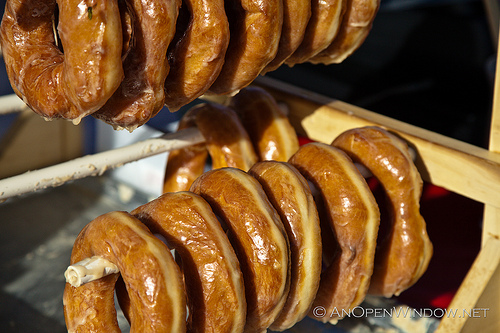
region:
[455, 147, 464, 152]
part of a table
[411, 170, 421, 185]
edge of a table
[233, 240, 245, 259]
part of a cake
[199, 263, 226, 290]
edge of a cake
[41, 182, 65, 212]
part of a rail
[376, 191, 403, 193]
edge of a cake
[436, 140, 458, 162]
edge of a table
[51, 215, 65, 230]
part of a table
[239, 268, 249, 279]
edge of a cake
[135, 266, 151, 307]
part of a cake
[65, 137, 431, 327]
A row of donuts on a stick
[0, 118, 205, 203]
A white glaze-covered stick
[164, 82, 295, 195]
Two donuts on the middle stick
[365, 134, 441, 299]
A lumpy donut in the back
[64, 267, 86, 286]
The end of the white stick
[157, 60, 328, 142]
A shadow cast on the donuts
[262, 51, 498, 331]
Wooden beams behind the donuts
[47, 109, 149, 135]
Signs of glaze dripping from the donuts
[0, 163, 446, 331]
A gray surface under the donuts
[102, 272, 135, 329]
The hole of a donut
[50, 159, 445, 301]
donuts are hanging on a stick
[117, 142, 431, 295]
donuts are golden brown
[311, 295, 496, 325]
the letters are white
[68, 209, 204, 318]
the donuts are glazed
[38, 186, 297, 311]
the donuts are shiny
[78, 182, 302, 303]
the donuts are reflecting the light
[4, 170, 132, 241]
the ground is blurry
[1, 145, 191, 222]
the stick is white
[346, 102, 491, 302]
the stick is attached to wood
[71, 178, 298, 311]
the donuts are sticky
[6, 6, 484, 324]
many donuts in rods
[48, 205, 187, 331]
donuts is color brown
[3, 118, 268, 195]
a white rod holding donuts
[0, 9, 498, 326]
support with white rods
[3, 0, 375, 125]
donuts color brown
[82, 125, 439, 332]
donuts are shining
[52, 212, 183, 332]
donuts has holes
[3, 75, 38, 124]
a white rod behind a donut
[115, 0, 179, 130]
a brown donut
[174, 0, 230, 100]
a brown donut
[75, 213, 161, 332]
donut on a rack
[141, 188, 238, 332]
donut on a rack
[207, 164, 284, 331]
donut on a rack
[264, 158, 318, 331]
donut on a rack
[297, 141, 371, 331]
donut on a rack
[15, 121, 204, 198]
white dowell to hold donuts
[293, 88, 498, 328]
wooden frame on a box to hold donuts to dry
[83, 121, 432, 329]
a row of drying glazed donuts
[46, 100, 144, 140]
glaze dripping off of donuts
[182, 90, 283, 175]
two donuts on a white dowell